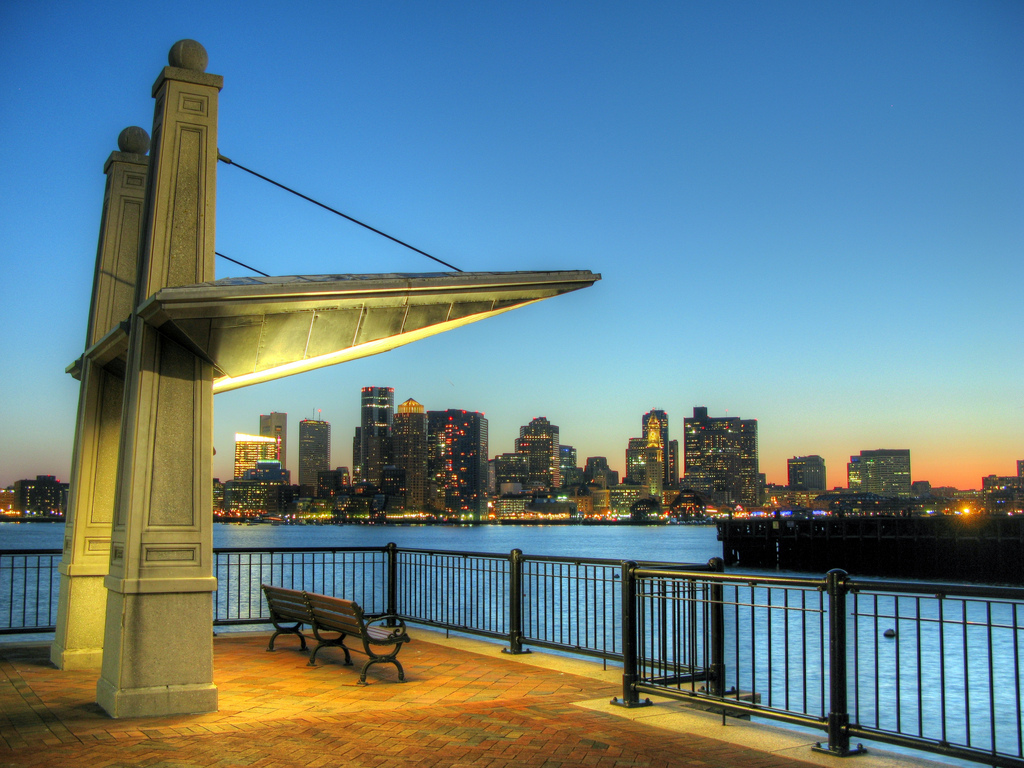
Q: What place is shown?
A: It is a river.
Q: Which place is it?
A: It is a river.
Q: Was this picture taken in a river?
A: Yes, it was taken in a river.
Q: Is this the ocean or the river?
A: It is the river.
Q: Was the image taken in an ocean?
A: No, the picture was taken in a river.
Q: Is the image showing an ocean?
A: No, the picture is showing a river.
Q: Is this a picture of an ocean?
A: No, the picture is showing a river.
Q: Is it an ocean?
A: No, it is a river.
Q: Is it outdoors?
A: Yes, it is outdoors.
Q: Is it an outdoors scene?
A: Yes, it is outdoors.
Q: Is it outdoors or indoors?
A: It is outdoors.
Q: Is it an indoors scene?
A: No, it is outdoors.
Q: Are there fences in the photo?
A: Yes, there is a fence.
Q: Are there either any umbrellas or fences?
A: Yes, there is a fence.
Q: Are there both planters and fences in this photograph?
A: No, there is a fence but no planters.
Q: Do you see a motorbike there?
A: No, there are no motorcycles.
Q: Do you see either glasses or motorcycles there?
A: No, there are no motorcycles or glasses.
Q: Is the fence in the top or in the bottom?
A: The fence is in the bottom of the image.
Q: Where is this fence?
A: The fence is at the dock.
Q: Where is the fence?
A: The fence is at the dock.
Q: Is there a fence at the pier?
A: Yes, there is a fence at the pier.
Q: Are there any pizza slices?
A: No, there are no pizza slices.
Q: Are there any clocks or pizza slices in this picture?
A: No, there are no pizza slices or clocks.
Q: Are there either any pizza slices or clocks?
A: No, there are no pizza slices or clocks.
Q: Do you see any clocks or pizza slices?
A: No, there are no pizza slices or clocks.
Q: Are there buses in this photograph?
A: No, there are no buses.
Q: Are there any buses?
A: No, there are no buses.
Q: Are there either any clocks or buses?
A: No, there are no buses or clocks.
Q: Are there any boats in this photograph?
A: Yes, there is a boat.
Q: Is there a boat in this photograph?
A: Yes, there is a boat.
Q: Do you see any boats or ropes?
A: Yes, there is a boat.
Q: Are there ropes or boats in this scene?
A: Yes, there is a boat.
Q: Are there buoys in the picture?
A: No, there are no buoys.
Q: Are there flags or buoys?
A: No, there are no buoys or flags.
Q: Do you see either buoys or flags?
A: No, there are no buoys or flags.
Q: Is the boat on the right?
A: Yes, the boat is on the right of the image.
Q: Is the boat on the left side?
A: No, the boat is on the right of the image.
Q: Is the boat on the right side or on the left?
A: The boat is on the right of the image.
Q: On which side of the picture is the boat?
A: The boat is on the right of the image.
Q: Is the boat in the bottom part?
A: Yes, the boat is in the bottom of the image.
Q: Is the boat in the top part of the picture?
A: No, the boat is in the bottom of the image.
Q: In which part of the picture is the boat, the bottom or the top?
A: The boat is in the bottom of the image.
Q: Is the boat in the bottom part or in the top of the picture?
A: The boat is in the bottom of the image.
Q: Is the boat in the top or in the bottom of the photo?
A: The boat is in the bottom of the image.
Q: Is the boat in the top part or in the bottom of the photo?
A: The boat is in the bottom of the image.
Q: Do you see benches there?
A: Yes, there is a bench.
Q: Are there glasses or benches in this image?
A: Yes, there is a bench.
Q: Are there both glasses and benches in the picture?
A: No, there is a bench but no glasses.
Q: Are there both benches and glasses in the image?
A: No, there is a bench but no glasses.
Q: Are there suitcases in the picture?
A: No, there are no suitcases.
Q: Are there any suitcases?
A: No, there are no suitcases.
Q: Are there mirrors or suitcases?
A: No, there are no suitcases or mirrors.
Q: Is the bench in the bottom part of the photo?
A: Yes, the bench is in the bottom of the image.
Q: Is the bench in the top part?
A: No, the bench is in the bottom of the image.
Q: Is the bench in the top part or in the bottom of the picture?
A: The bench is in the bottom of the image.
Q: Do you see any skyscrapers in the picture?
A: Yes, there are skyscrapers.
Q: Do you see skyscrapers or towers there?
A: Yes, there are skyscrapers.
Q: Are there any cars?
A: No, there are no cars.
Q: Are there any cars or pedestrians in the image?
A: No, there are no cars or pedestrians.